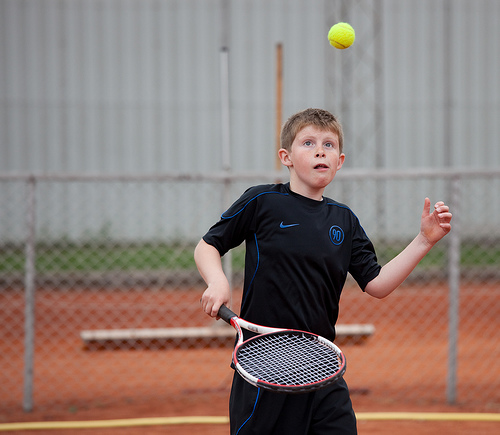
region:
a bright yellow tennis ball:
[326, 18, 353, 54]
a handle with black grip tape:
[199, 290, 240, 325]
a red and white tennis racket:
[208, 303, 348, 398]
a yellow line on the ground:
[11, 411, 228, 431]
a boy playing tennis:
[185, 95, 459, 434]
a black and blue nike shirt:
[205, 181, 384, 352]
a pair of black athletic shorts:
[228, 362, 361, 434]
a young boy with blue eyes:
[186, 106, 456, 433]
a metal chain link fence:
[11, 168, 498, 407]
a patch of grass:
[13, 227, 483, 291]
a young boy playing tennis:
[191, 108, 451, 433]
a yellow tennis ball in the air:
[326, 21, 354, 49]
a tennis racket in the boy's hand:
[198, 295, 345, 392]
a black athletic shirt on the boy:
[201, 182, 382, 377]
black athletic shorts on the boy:
[228, 365, 357, 433]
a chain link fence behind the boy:
[0, 170, 499, 409]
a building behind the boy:
[0, 0, 499, 242]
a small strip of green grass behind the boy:
[0, 234, 499, 269]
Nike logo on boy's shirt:
[278, 221, 302, 229]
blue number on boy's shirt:
[328, 225, 345, 245]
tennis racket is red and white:
[225, 323, 315, 411]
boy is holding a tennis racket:
[194, 285, 236, 326]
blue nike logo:
[275, 212, 295, 227]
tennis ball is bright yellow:
[322, 22, 362, 60]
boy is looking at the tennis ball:
[286, 130, 354, 150]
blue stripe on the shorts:
[242, 380, 269, 411]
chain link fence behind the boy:
[28, 160, 65, 277]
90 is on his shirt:
[321, 212, 348, 245]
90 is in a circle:
[332, 220, 342, 241]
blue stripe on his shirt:
[236, 261, 275, 289]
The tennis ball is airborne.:
[326, 21, 355, 51]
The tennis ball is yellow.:
[327, 20, 356, 50]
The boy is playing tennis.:
[193, 109, 450, 434]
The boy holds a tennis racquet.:
[201, 289, 346, 394]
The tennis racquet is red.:
[219, 305, 344, 394]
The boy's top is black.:
[203, 184, 378, 341]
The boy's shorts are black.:
[231, 391, 352, 433]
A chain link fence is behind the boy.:
[0, 175, 190, 415]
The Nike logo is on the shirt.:
[277, 219, 302, 230]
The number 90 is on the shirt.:
[331, 228, 341, 244]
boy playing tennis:
[186, 7, 460, 429]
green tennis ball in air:
[297, 8, 399, 95]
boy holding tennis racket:
[182, 91, 455, 431]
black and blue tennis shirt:
[184, 161, 424, 403]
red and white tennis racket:
[168, 263, 362, 410]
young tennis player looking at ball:
[175, 5, 465, 415]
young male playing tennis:
[193, 83, 430, 433]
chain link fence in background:
[45, 143, 227, 361]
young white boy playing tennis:
[170, 84, 487, 409]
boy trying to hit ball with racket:
[190, 78, 455, 410]